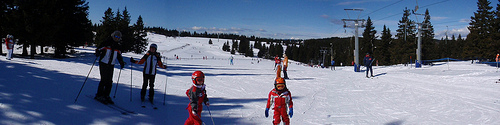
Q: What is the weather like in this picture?
A: It is clear.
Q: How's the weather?
A: It is clear.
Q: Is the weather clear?
A: Yes, it is clear.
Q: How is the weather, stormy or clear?
A: It is clear.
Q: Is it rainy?
A: No, it is clear.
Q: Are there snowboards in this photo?
A: No, there are no snowboards.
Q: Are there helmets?
A: Yes, there is a helmet.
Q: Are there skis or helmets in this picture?
A: Yes, there is a helmet.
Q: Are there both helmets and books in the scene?
A: No, there is a helmet but no books.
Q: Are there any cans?
A: No, there are no cans.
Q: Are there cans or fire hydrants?
A: No, there are no cans or fire hydrants.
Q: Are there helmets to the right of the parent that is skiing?
A: Yes, there is a helmet to the right of the parent.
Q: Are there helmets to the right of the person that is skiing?
A: Yes, there is a helmet to the right of the parent.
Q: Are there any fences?
A: No, there are no fences.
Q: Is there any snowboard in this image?
A: No, there are no snowboards.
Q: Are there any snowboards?
A: No, there are no snowboards.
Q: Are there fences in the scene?
A: No, there are no fences.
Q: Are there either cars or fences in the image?
A: No, there are no fences or cars.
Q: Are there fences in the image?
A: No, there are no fences.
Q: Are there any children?
A: Yes, there is a child.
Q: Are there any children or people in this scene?
A: Yes, there is a child.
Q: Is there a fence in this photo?
A: No, there are no fences.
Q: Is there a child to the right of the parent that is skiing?
A: Yes, there is a child to the right of the parent.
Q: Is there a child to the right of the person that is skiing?
A: Yes, there is a child to the right of the parent.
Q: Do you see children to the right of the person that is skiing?
A: Yes, there is a child to the right of the parent.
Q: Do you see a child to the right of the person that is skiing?
A: Yes, there is a child to the right of the parent.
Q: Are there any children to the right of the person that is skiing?
A: Yes, there is a child to the right of the parent.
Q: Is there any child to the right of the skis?
A: Yes, there is a child to the right of the skis.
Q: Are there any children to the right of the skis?
A: Yes, there is a child to the right of the skis.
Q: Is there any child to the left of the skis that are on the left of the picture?
A: No, the child is to the right of the skis.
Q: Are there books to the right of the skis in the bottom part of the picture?
A: No, there is a child to the right of the skis.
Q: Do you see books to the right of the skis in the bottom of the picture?
A: No, there is a child to the right of the skis.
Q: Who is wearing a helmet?
A: The kid is wearing a helmet.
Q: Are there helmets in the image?
A: Yes, there is a helmet.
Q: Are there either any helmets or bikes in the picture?
A: Yes, there is a helmet.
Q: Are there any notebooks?
A: No, there are no notebooks.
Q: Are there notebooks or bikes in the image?
A: No, there are no notebooks or bikes.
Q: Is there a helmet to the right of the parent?
A: Yes, there is a helmet to the right of the parent.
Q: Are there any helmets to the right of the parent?
A: Yes, there is a helmet to the right of the parent.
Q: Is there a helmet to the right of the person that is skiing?
A: Yes, there is a helmet to the right of the parent.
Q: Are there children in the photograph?
A: Yes, there is a child.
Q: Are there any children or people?
A: Yes, there is a child.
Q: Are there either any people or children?
A: Yes, there is a child.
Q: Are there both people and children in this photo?
A: Yes, there are both a child and a person.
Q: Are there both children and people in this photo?
A: Yes, there are both a child and a person.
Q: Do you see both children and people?
A: Yes, there are both a child and a person.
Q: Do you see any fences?
A: No, there are no fences.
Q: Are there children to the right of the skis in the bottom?
A: Yes, there is a child to the right of the skis.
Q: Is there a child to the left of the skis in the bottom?
A: No, the child is to the right of the skis.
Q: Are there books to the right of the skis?
A: No, there is a child to the right of the skis.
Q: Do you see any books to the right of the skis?
A: No, there is a child to the right of the skis.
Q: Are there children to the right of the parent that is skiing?
A: Yes, there is a child to the right of the parent.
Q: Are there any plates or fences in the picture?
A: No, there are no fences or plates.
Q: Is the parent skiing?
A: Yes, the parent is skiing.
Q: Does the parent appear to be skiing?
A: Yes, the parent is skiing.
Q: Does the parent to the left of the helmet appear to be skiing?
A: Yes, the parent is skiing.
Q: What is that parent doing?
A: The parent is skiing.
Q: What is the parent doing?
A: The parent is skiing.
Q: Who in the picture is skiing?
A: The parent is skiing.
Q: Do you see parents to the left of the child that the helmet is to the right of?
A: Yes, there is a parent to the left of the child.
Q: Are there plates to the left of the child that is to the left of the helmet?
A: No, there is a parent to the left of the kid.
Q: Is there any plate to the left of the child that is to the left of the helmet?
A: No, there is a parent to the left of the kid.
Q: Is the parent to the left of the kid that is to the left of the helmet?
A: Yes, the parent is to the left of the kid.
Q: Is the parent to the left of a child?
A: Yes, the parent is to the left of a child.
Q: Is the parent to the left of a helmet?
A: Yes, the parent is to the left of a helmet.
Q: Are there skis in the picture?
A: Yes, there are skis.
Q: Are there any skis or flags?
A: Yes, there are skis.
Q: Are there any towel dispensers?
A: No, there are no towel dispensers.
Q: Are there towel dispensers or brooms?
A: No, there are no towel dispensers or brooms.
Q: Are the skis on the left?
A: Yes, the skis are on the left of the image.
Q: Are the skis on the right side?
A: No, the skis are on the left of the image.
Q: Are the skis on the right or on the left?
A: The skis are on the left of the image.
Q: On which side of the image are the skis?
A: The skis are on the left of the image.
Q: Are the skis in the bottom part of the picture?
A: Yes, the skis are in the bottom of the image.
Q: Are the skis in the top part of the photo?
A: No, the skis are in the bottom of the image.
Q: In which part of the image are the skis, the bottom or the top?
A: The skis are in the bottom of the image.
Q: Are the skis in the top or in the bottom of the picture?
A: The skis are in the bottom of the image.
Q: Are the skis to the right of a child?
A: No, the skis are to the left of a child.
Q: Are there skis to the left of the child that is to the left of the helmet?
A: Yes, there are skis to the left of the child.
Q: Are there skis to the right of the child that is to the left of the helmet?
A: No, the skis are to the left of the kid.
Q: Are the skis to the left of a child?
A: Yes, the skis are to the left of a child.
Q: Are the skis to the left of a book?
A: No, the skis are to the left of a child.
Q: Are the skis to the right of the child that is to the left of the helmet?
A: No, the skis are to the left of the child.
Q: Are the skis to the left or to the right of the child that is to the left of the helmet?
A: The skis are to the left of the kid.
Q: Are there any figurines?
A: No, there are no figurines.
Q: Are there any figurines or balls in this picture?
A: No, there are no figurines or balls.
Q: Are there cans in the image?
A: No, there are no cans.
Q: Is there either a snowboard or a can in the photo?
A: No, there are no cans or snowboards.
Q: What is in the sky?
A: The clouds are in the sky.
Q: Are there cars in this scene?
A: No, there are no cars.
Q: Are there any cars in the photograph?
A: No, there are no cars.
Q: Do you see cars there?
A: No, there are no cars.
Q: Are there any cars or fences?
A: No, there are no cars or fences.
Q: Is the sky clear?
A: Yes, the sky is clear.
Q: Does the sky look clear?
A: Yes, the sky is clear.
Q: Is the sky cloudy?
A: No, the sky is clear.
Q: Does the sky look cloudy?
A: No, the sky is clear.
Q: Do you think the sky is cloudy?
A: No, the sky is clear.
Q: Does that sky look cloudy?
A: No, the sky is clear.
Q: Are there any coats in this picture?
A: Yes, there is a coat.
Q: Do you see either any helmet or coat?
A: Yes, there is a coat.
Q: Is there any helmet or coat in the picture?
A: Yes, there is a coat.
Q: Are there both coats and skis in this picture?
A: Yes, there are both a coat and skis.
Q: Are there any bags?
A: No, there are no bags.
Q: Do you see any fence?
A: No, there are no fences.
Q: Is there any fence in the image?
A: No, there are no fences.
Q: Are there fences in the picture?
A: No, there are no fences.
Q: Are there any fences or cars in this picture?
A: No, there are no fences or cars.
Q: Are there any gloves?
A: Yes, there are gloves.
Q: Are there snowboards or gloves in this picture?
A: Yes, there are gloves.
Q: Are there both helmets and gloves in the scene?
A: Yes, there are both gloves and a helmet.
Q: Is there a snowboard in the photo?
A: No, there are no snowboards.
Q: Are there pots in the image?
A: No, there are no pots.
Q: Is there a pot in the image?
A: No, there are no pots.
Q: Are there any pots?
A: No, there are no pots.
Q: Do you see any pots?
A: No, there are no pots.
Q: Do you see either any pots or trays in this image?
A: No, there are no pots or trays.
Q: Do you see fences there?
A: No, there are no fences.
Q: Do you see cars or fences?
A: No, there are no fences or cars.